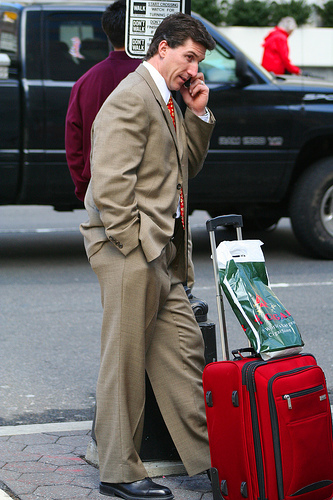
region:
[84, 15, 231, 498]
man talking on phone on street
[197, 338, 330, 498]
red luggage by a man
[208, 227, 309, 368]
shopping bag on luggage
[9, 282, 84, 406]
paved street in a city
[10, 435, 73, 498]
concrete pavers on a sidewalk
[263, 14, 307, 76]
pedestrian on a sidewalk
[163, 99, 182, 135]
red tie on a man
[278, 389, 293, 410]
zipper on red luggage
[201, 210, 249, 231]
handle on red luggage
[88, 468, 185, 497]
right shoe of a man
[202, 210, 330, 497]
Suitcase on the ground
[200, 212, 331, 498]
Red suitcase on the ground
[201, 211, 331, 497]
Rolling suitcase on the ground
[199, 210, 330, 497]
Red rolling suitcase on the ground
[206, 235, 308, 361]
Bag on top of suitcase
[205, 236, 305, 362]
Bag on top of rolling suitcase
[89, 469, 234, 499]
Man is wearing shoes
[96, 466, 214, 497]
Man is wearing black shoes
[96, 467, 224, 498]
Man is wearing dress shoes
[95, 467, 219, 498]
Man is wearing black dress shoes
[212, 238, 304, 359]
Green plastic shopping bag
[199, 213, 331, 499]
Red suitcase on wheels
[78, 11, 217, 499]
Man talking on his cellphone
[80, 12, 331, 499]
Man standing behind his luggage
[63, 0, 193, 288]
Man wearing a burgundy long sleeve shirt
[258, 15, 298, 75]
Gray haired woman wearing a red jacket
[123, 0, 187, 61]
White instructional crossing sign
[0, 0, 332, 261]
Black pickup truck driving on the road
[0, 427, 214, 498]
Hexagonal stone tiled sidewalk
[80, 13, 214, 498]
Man wearing a brown suit and red tie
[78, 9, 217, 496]
A MAN TALKING ON HIS CELL PHONE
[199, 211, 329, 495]
RED ROLLING LUGGAGE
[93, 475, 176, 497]
A MAN'S BLACK SHOE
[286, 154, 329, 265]
A FRONT TRUNK TIRE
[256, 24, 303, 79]
A RED JACKET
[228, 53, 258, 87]
A SIDE VIEW MIRROR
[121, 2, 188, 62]
A BLACK AND WHITE STREET SIGN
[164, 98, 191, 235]
A RED AND WHITE TIE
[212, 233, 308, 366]
A PLASTIC BAG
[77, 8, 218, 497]
A MAN WEARING A SUIT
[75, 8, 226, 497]
Man talking on a cell phone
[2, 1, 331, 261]
Black truck behind the man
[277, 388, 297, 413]
Zipper on the red bag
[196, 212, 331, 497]
Plastic bag on red suitcase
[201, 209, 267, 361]
Handle on red bag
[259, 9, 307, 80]
Person wearing a red jacket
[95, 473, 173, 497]
A black leather shoe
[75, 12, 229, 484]
Man wearing a brown suit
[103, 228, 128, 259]
Buttons on jacket sleeve